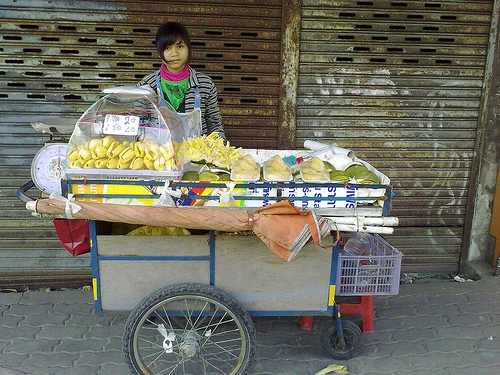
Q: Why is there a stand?
A: For sales.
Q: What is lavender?
A: A basket.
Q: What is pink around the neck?
A: A scarf.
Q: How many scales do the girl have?
A: One.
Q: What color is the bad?
A: Red.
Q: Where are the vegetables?
A: On stand.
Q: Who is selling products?
A: A girl.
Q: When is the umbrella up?
A: On hot day.